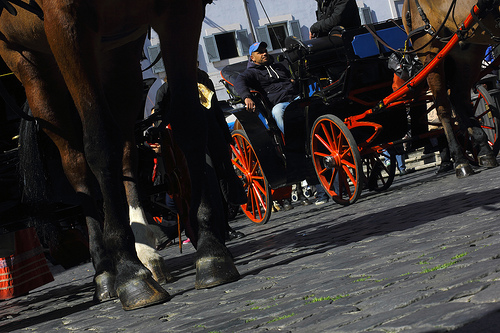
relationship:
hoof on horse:
[185, 250, 255, 291] [5, 2, 247, 294]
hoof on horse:
[113, 270, 179, 319] [5, 2, 247, 294]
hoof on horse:
[88, 265, 130, 307] [5, 2, 247, 294]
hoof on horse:
[133, 245, 170, 287] [5, 2, 247, 294]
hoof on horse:
[448, 160, 479, 182] [388, 2, 498, 187]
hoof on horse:
[471, 153, 498, 172] [388, 2, 498, 187]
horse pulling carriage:
[0, 0, 242, 312] [222, 4, 481, 227]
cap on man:
[245, 39, 270, 54] [240, 40, 313, 132]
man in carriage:
[240, 40, 313, 132] [224, 50, 422, 227]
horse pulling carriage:
[402, 2, 498, 179] [225, 10, 421, 222]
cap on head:
[248, 41, 268, 54] [248, 40, 270, 63]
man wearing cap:
[233, 41, 301, 135] [248, 39, 267, 57]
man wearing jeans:
[233, 41, 301, 135] [265, 95, 300, 145]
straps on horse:
[402, 3, 442, 52] [42, 6, 257, 243]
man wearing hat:
[233, 41, 301, 135] [246, 37, 268, 60]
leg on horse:
[44, 21, 173, 313] [5, 2, 247, 294]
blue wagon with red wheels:
[217, 19, 407, 227] [229, 113, 364, 224]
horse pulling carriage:
[402, 2, 498, 179] [218, 22, 400, 108]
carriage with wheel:
[218, 22, 400, 108] [309, 116, 361, 207]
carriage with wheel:
[218, 22, 400, 108] [371, 149, 396, 188]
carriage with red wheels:
[218, 22, 400, 108] [229, 130, 271, 225]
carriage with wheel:
[218, 22, 400, 108] [470, 82, 497, 149]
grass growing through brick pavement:
[308, 292, 344, 302] [0, 166, 498, 331]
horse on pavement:
[5, 2, 247, 294] [7, 143, 497, 331]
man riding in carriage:
[233, 41, 301, 135] [222, 26, 418, 218]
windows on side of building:
[203, 15, 307, 67] [127, 2, 423, 135]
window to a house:
[212, 28, 239, 63] [145, 4, 410, 144]